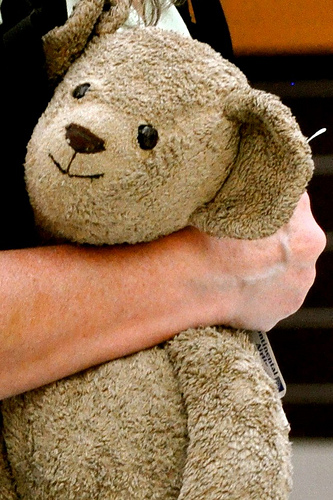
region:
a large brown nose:
[46, 115, 115, 160]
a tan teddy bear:
[33, 9, 281, 499]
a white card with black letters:
[237, 323, 293, 404]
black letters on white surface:
[249, 331, 278, 386]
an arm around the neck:
[16, 211, 298, 370]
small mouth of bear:
[47, 147, 122, 188]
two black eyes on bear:
[67, 77, 165, 162]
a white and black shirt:
[14, 2, 230, 133]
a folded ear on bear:
[44, 12, 105, 73]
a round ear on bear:
[209, 75, 303, 284]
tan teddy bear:
[1, 0, 316, 499]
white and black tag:
[238, 327, 292, 408]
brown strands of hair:
[112, 1, 191, 24]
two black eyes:
[68, 70, 161, 151]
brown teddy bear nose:
[59, 120, 108, 159]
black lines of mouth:
[39, 145, 110, 181]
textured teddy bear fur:
[87, 404, 150, 476]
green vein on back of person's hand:
[274, 233, 293, 278]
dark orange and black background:
[219, 0, 331, 88]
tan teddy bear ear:
[192, 78, 316, 247]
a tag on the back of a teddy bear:
[250, 330, 287, 398]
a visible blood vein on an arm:
[188, 232, 295, 293]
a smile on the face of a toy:
[48, 152, 104, 178]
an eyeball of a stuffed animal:
[135, 124, 158, 151]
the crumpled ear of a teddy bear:
[42, 1, 132, 74]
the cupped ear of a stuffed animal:
[188, 89, 312, 241]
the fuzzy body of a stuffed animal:
[1, 325, 295, 498]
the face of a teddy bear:
[24, 27, 247, 244]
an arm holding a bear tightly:
[0, 184, 328, 399]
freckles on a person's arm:
[1, 234, 182, 328]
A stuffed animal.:
[2, 1, 317, 498]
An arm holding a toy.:
[0, 179, 327, 388]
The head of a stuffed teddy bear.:
[15, 1, 322, 256]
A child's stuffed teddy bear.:
[1, 3, 317, 404]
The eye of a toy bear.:
[64, 76, 97, 106]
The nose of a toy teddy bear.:
[60, 120, 106, 157]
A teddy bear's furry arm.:
[167, 322, 300, 498]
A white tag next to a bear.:
[246, 326, 292, 405]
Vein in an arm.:
[201, 231, 297, 290]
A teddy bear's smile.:
[45, 116, 110, 180]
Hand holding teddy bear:
[0, 4, 331, 397]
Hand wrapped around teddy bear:
[0, 1, 315, 412]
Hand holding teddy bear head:
[3, 1, 319, 410]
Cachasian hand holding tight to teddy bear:
[3, 2, 327, 421]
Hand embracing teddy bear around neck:
[0, 3, 324, 422]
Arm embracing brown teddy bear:
[0, 2, 321, 422]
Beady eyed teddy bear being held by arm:
[0, 1, 324, 433]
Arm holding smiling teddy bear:
[0, 2, 327, 450]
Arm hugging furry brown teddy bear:
[4, 5, 325, 450]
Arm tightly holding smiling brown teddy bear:
[0, 11, 331, 463]